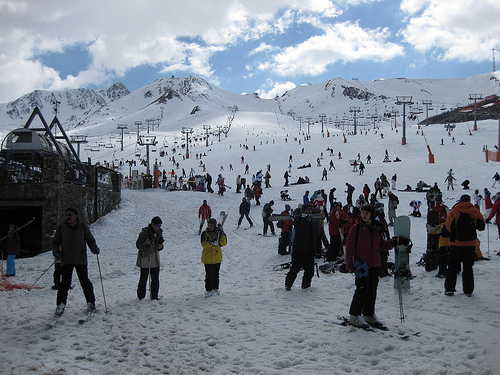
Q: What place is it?
A: It is a field.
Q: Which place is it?
A: It is a field.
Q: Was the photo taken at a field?
A: Yes, it was taken in a field.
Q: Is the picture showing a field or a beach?
A: It is showing a field.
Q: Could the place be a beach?
A: No, it is a field.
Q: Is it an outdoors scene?
A: Yes, it is outdoors.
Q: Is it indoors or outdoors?
A: It is outdoors.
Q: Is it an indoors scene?
A: No, it is outdoors.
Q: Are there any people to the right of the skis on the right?
A: Yes, there is a person to the right of the skis.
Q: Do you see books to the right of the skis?
A: No, there is a person to the right of the skis.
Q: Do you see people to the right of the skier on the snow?
A: Yes, there is a person to the right of the skier.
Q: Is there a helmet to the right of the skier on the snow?
A: No, there is a person to the right of the skier.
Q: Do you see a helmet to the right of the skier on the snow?
A: No, there is a person to the right of the skier.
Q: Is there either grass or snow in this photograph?
A: Yes, there is snow.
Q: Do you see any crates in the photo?
A: No, there are no crates.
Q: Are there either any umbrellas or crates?
A: No, there are no crates or umbrellas.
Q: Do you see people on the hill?
A: Yes, there is a person on the hill.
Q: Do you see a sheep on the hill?
A: No, there is a person on the hill.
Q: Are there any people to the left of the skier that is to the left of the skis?
A: Yes, there is a person to the left of the skier.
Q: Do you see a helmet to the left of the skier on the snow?
A: No, there is a person to the left of the skier.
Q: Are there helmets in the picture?
A: No, there are no helmets.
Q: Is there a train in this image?
A: Yes, there is a train.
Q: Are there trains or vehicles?
A: Yes, there is a train.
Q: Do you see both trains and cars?
A: No, there is a train but no cars.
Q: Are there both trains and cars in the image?
A: No, there is a train but no cars.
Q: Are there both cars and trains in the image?
A: No, there is a train but no cars.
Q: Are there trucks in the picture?
A: No, there are no trucks.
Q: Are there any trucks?
A: No, there are no trucks.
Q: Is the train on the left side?
A: Yes, the train is on the left of the image.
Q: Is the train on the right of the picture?
A: No, the train is on the left of the image.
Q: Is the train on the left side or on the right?
A: The train is on the left of the image.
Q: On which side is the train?
A: The train is on the left of the image.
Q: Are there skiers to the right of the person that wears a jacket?
A: Yes, there is a skier to the right of the person.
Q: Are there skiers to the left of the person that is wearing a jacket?
A: No, the skier is to the right of the person.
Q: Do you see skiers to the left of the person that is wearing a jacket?
A: No, the skier is to the right of the person.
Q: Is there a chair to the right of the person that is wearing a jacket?
A: No, there is a skier to the right of the person.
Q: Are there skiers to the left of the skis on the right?
A: Yes, there is a skier to the left of the skis.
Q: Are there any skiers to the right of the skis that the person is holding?
A: No, the skier is to the left of the skis.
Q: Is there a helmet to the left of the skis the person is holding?
A: No, there is a skier to the left of the skis.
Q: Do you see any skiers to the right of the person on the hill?
A: Yes, there is a skier to the right of the person.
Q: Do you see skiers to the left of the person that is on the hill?
A: No, the skier is to the right of the person.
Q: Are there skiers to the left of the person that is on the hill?
A: No, the skier is to the right of the person.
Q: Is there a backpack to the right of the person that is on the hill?
A: No, there is a skier to the right of the person.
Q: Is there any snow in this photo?
A: Yes, there is snow.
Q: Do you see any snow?
A: Yes, there is snow.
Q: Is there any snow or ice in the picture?
A: Yes, there is snow.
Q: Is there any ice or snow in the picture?
A: Yes, there is snow.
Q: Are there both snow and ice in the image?
A: No, there is snow but no ice.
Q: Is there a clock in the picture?
A: No, there are no clocks.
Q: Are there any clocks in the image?
A: No, there are no clocks.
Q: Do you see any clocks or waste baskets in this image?
A: No, there are no clocks or waste baskets.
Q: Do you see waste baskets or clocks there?
A: No, there are no clocks or waste baskets.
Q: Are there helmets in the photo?
A: No, there are no helmets.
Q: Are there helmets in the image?
A: No, there are no helmets.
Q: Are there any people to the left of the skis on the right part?
A: Yes, there is a person to the left of the skis.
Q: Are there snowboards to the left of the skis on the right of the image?
A: No, there is a person to the left of the skis.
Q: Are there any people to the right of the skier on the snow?
A: Yes, there is a person to the right of the skier.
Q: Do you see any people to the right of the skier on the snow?
A: Yes, there is a person to the right of the skier.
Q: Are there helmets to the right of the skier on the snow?
A: No, there is a person to the right of the skier.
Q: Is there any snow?
A: Yes, there is snow.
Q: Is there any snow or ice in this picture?
A: Yes, there is snow.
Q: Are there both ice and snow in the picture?
A: No, there is snow but no ice.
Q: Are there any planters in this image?
A: No, there are no planters.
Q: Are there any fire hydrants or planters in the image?
A: No, there are no planters or fire hydrants.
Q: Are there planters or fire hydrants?
A: No, there are no planters or fire hydrants.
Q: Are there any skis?
A: Yes, there are skis.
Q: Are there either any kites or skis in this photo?
A: Yes, there are skis.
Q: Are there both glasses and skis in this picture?
A: No, there are skis but no glasses.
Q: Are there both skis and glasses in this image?
A: No, there are skis but no glasses.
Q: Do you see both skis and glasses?
A: No, there are skis but no glasses.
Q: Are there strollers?
A: No, there are no strollers.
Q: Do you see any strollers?
A: No, there are no strollers.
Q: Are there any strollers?
A: No, there are no strollers.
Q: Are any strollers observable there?
A: No, there are no strollers.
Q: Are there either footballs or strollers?
A: No, there are no strollers or footballs.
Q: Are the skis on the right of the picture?
A: Yes, the skis are on the right of the image.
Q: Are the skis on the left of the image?
A: No, the skis are on the right of the image.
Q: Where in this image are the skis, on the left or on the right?
A: The skis are on the right of the image.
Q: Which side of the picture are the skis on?
A: The skis are on the right of the image.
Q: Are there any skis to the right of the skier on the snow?
A: Yes, there are skis to the right of the skier.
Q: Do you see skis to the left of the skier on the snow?
A: No, the skis are to the right of the skier.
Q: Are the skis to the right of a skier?
A: Yes, the skis are to the right of a skier.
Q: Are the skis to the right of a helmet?
A: No, the skis are to the right of a skier.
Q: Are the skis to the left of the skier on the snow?
A: No, the skis are to the right of the skier.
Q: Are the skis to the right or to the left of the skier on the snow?
A: The skis are to the right of the skier.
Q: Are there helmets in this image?
A: No, there are no helmets.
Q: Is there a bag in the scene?
A: No, there are no bags.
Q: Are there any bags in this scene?
A: No, there are no bags.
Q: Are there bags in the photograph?
A: No, there are no bags.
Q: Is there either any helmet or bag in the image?
A: No, there are no bags or helmets.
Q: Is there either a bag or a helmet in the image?
A: No, there are no bags or helmets.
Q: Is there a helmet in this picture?
A: No, there are no helmets.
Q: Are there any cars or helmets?
A: No, there are no helmets or cars.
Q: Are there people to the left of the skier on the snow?
A: Yes, there is a person to the left of the skier.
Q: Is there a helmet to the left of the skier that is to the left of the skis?
A: No, there is a person to the left of the skier.